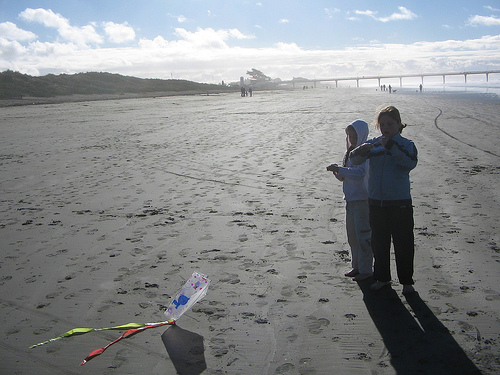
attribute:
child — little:
[324, 117, 369, 282]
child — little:
[351, 108, 415, 292]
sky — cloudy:
[1, 3, 499, 95]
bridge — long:
[225, 66, 499, 97]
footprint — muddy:
[344, 312, 356, 323]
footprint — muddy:
[316, 294, 333, 305]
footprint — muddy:
[322, 239, 339, 245]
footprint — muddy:
[331, 216, 340, 225]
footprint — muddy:
[298, 273, 310, 281]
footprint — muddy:
[252, 318, 271, 326]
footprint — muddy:
[460, 285, 471, 296]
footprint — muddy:
[241, 233, 249, 243]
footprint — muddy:
[127, 235, 141, 242]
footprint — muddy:
[206, 206, 216, 216]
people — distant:
[378, 83, 393, 94]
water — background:
[392, 72, 497, 93]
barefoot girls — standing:
[323, 104, 416, 289]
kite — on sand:
[69, 269, 223, 374]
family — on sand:
[327, 90, 427, 302]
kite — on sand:
[31, 273, 225, 360]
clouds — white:
[5, 7, 253, 83]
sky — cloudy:
[0, 0, 496, 80]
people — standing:
[328, 110, 429, 303]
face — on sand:
[378, 113, 402, 142]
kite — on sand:
[23, 239, 240, 371]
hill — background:
[16, 72, 91, 99]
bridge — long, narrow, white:
[264, 43, 497, 107]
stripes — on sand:
[366, 139, 401, 151]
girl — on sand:
[301, 85, 416, 327]